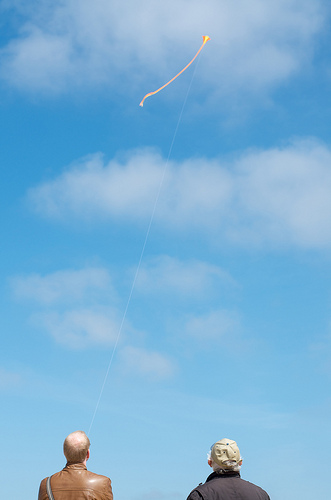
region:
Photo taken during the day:
[17, 4, 323, 486]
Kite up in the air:
[135, 0, 241, 103]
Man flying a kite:
[30, 433, 130, 491]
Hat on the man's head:
[204, 430, 249, 472]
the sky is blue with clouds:
[24, 0, 312, 478]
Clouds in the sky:
[61, 137, 290, 350]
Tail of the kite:
[137, 44, 211, 113]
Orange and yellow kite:
[202, 26, 210, 51]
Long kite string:
[82, 46, 207, 450]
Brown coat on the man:
[21, 449, 122, 498]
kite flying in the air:
[132, 26, 217, 113]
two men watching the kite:
[36, 425, 257, 499]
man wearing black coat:
[186, 430, 268, 499]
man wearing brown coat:
[33, 430, 114, 499]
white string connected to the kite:
[79, 67, 209, 443]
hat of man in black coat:
[208, 439, 238, 467]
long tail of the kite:
[137, 46, 208, 114]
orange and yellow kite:
[201, 33, 210, 41]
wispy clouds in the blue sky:
[21, 137, 330, 366]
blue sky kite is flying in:
[4, 5, 322, 422]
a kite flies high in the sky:
[135, 30, 212, 110]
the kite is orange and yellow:
[133, 31, 219, 109]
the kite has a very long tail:
[134, 29, 214, 107]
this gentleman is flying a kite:
[34, 425, 118, 498]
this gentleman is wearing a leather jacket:
[34, 427, 120, 498]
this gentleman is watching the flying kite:
[182, 435, 273, 498]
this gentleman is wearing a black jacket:
[182, 435, 275, 498]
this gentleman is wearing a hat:
[204, 432, 246, 475]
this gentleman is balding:
[59, 430, 92, 465]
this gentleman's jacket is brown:
[34, 458, 118, 498]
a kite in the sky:
[121, 18, 231, 102]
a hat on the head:
[188, 421, 244, 468]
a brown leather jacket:
[29, 459, 112, 498]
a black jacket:
[182, 467, 281, 497]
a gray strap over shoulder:
[34, 465, 68, 498]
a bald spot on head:
[62, 425, 87, 448]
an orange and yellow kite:
[112, 22, 223, 107]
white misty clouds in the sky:
[26, 18, 329, 265]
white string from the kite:
[90, 40, 220, 442]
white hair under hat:
[193, 438, 248, 482]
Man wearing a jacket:
[33, 461, 126, 497]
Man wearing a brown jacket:
[37, 460, 114, 498]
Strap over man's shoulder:
[45, 472, 52, 497]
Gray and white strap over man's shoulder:
[43, 471, 55, 498]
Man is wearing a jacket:
[178, 468, 275, 499]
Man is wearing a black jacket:
[183, 467, 273, 498]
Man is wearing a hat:
[208, 434, 243, 468]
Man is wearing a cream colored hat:
[208, 437, 241, 467]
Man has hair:
[205, 446, 243, 471]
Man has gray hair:
[205, 450, 245, 473]